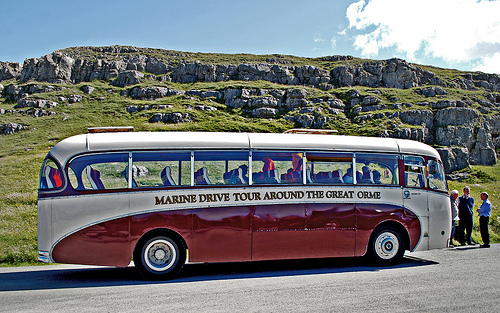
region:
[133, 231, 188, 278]
Wheel on a bus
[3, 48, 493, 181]
Rocky hills in the background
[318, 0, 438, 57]
Wispy clouds in the sky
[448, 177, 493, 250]
People gathered next to a bus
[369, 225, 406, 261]
Front wheel of a bus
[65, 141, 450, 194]
Windows on the side of a bus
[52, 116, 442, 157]
Roof of a bus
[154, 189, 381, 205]
Words on the side of a bus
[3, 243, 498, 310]
Gray paved road for vehicles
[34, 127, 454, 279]
A red and silver tour bus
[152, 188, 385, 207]
Red text on a silver background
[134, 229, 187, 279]
The back tire of a bus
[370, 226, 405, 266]
The front tire of a bus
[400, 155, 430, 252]
A bus door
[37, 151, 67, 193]
The back window of a bus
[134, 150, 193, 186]
A bus window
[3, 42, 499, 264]
A rocky landscape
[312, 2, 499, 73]
A white fluffy cloud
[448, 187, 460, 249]
A man standing in front of a bus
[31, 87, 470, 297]
this is a bus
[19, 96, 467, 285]
this is a vintage bus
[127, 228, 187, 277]
the rear wheel of the bus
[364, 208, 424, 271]
this is a front wheel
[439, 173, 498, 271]
three men standing outside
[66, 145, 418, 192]
a row of bus windows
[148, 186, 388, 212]
words on the side of the bus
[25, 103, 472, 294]
the bus is shiny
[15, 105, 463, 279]
the bus is red and white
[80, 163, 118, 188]
a set of seats on the bus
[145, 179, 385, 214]
long label on side of bus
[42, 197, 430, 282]
bottom of bus is red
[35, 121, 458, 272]
an old fashioned looking bus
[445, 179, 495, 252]
people standing in front of bus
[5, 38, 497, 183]
a rocky landscape next to a road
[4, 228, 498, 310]
a road next to a rocky landscape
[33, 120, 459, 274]
a bus parked on the side of a road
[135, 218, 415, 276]
the bus has two wheels on one side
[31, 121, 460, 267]
the bus is white and red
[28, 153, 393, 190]
the seats of the bus are red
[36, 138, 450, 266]
red and white bus in the street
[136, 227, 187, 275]
small black front wheel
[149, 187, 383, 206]
black letters on white part of bus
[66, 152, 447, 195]
a buch of windows in right side of bus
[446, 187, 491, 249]
three people standing in front of the bus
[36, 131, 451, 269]
bus parked in the street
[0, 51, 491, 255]
small mountain cover with rocks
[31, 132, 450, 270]
red and white marine bus